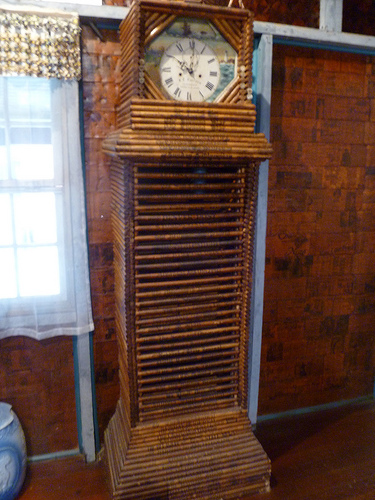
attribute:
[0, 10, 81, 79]
decorations — silver, gold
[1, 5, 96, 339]
curtain — white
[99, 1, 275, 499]
clock holder — wooden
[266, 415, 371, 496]
floor sheet — brown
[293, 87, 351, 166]
tiles — brown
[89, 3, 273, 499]
clock — wood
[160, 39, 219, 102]
clock — white, 10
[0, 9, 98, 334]
curtains — white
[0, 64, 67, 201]
window — white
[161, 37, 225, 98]
numerals — Roman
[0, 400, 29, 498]
pot — white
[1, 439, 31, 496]
designs — blue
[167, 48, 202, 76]
hands — big, little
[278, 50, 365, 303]
cork wall — brown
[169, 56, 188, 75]
hand — hour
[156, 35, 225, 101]
clock — white, small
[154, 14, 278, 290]
clock — grandfather, wooden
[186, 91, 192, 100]
number — VI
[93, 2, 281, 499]
stand — wooden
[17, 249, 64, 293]
pane — glass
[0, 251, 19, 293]
pane — glass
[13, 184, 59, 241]
pane — glass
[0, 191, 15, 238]
pane — glass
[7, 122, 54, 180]
pane — glass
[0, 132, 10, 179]
pane — glass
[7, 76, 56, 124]
pane — glass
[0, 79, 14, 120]
pane — glass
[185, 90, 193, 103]
vi — upside down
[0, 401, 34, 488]
vase — blue, white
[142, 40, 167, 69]
design — duck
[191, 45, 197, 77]
hand — minute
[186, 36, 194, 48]
numerals — roman